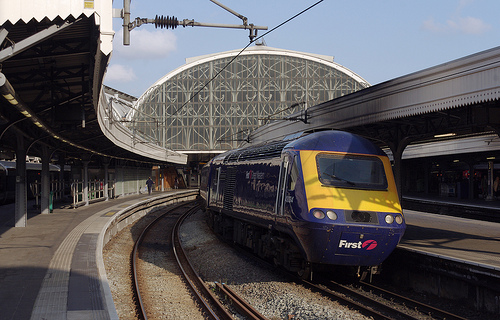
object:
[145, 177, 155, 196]
man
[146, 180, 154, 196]
clothing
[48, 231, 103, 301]
stone square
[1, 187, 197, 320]
platform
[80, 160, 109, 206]
white rails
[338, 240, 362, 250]
word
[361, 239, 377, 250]
logo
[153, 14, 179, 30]
electrical coil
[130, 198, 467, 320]
tracks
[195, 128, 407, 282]
train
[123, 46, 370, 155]
structure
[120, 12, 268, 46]
pole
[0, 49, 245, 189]
metal awning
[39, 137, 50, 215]
pole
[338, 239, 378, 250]
logo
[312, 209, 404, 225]
headlights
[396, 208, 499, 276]
station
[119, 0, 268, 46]
holder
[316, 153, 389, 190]
window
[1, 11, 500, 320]
station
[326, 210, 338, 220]
headlight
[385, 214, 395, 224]
headlight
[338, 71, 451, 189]
depo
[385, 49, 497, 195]
station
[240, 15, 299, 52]
wire